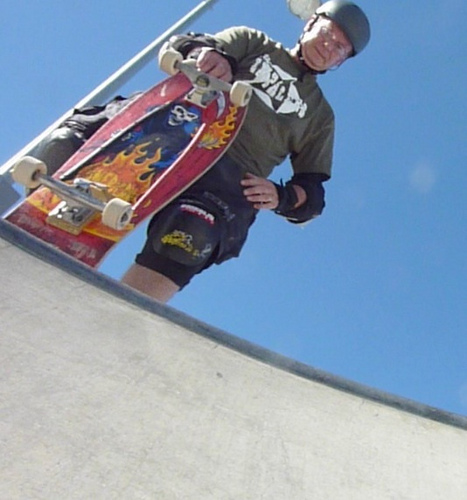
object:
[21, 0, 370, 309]
man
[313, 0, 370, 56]
helmet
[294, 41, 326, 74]
chin strap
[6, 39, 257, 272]
skateboard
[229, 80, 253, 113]
wheel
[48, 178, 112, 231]
trucks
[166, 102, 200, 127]
face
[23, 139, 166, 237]
flame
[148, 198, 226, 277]
knee pad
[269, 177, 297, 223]
wrist guards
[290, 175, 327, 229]
elbow pad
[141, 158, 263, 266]
shorts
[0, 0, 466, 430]
sky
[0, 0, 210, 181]
pole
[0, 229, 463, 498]
ramp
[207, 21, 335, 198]
shirt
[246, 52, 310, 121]
white picture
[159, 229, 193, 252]
picture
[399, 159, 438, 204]
clouds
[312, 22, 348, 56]
eyeglasses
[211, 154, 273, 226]
hip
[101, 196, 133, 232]
back wheels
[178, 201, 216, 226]
letters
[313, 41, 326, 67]
lip